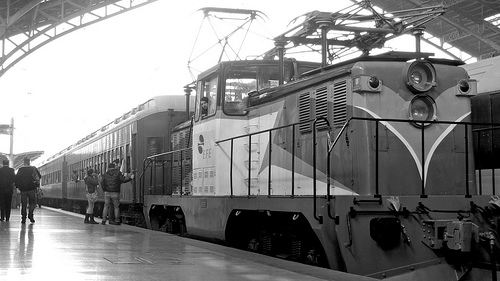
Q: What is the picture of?
A: Engine of the train.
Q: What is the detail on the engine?
A: V shape.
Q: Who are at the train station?
A: Passengers.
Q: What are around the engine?
A: Black hand rails.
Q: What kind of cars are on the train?
A: Passenger.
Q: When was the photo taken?
A: During the daytime.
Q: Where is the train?
A: On the tracks.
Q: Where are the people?
A: Next to train.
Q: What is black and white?
A: The whole photo.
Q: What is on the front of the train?
A: Windows.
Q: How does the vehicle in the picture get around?
A: It runs on tracks.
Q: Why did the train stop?
A: So the people could get on.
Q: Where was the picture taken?
A: At a train station.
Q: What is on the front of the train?
A: A light.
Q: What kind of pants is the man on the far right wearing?
A: Jeans.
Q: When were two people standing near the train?
A: While it was stopped.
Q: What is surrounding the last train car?
A: A fence.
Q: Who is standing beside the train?
A: A man and a woman.